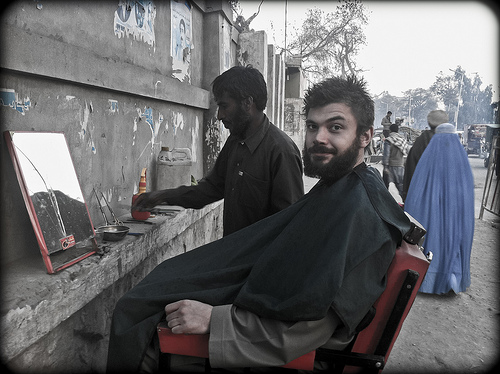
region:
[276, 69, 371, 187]
man has dark hair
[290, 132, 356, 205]
man has facial hair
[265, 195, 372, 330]
man wears black cape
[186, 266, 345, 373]
man wears grey shirt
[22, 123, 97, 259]
mirror in front of man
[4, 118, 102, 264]
mirror on stone shelf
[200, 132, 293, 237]
man has black shirt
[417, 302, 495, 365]
light grey concrete on street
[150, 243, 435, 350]
man sits on red chair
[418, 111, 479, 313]
woman has blue headscarf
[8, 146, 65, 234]
crack in the mirror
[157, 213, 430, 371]
red barber shop chair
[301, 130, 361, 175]
man's black beard and mustache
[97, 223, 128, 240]
metal wash bowl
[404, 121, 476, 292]
woman in a blue dress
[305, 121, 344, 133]
man has brown eyes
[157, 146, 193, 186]
gray storage jug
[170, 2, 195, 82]
advertisement on the wall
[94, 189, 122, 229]
two scissors leaning against the wall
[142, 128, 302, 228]
dark long sleeve collared shirt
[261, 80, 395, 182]
the man has a beard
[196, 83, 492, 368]
the man is sitting in a chair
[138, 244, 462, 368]
the chair is red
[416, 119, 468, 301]
the outfit is blue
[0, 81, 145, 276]
the mirror is broken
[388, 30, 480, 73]
the sky seems cloudy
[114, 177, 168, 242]
the cup is red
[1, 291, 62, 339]
the wall is gray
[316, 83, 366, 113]
the mans hair is spiked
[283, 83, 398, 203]
the man has a mustache.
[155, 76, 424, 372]
man sitting on a red chair outside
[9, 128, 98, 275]
cracked mirror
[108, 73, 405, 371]
man wearing a black cape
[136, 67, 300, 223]
man wearing a black shirt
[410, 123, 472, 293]
woman wearing blue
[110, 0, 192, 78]
old posters on the side of a building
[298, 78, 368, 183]
man with a beard looking at the camera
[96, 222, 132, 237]
silver bowl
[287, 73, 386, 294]
man sitting in a chair and looking at the camera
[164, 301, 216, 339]
man's hand resting on the arm of the red chair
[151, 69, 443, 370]
Man sitting in chair.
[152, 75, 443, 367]
Man getting hair cut.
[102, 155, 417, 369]
black cape on person.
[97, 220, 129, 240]
Metal bowl on ledge.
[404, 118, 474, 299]
woman in blue covering.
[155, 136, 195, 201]
White jug on ledge.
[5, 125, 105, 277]
Mirror on the ledge.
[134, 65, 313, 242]
Man standing behind chair.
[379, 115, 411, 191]
man walking on the sidewalk.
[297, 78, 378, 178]
Beard on the man.